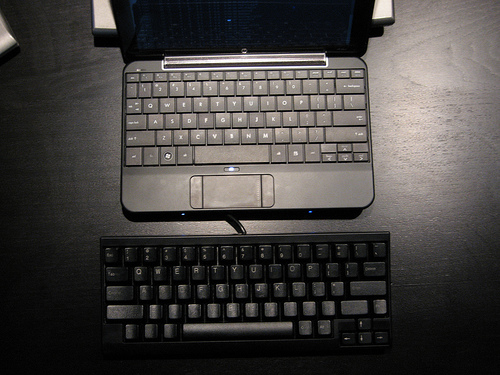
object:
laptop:
[107, 0, 377, 218]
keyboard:
[118, 56, 376, 216]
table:
[0, 0, 500, 375]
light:
[308, 210, 313, 213]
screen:
[107, 0, 377, 64]